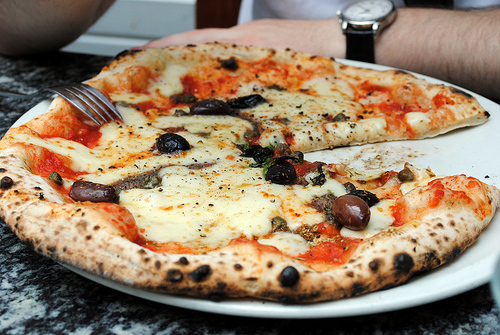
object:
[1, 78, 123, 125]
fork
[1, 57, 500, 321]
plate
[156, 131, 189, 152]
black olive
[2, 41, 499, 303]
pizza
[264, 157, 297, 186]
black olive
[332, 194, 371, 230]
black olive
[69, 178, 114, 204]
black olive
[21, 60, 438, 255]
cheese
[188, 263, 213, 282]
burnt spots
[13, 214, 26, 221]
burnt spots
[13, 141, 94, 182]
tomato sauce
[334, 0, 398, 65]
watch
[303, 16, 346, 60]
wrist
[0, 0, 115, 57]
elbow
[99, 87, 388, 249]
seasoning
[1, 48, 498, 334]
counter top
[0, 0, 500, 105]
person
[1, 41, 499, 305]
crust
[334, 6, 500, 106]
arm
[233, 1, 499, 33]
shirt